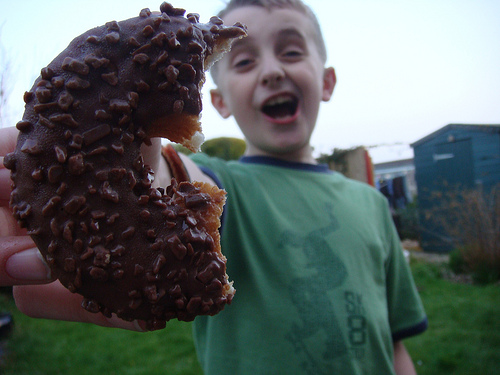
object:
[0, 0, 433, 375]
boy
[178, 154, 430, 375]
shirt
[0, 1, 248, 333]
doughnut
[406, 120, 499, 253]
shed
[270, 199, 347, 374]
design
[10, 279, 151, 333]
fingers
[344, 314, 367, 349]
number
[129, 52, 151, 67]
sprinkle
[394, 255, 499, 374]
grass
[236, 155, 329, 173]
collar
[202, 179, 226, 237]
strip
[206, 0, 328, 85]
hair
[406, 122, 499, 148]
roof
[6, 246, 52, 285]
fingernail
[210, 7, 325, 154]
face